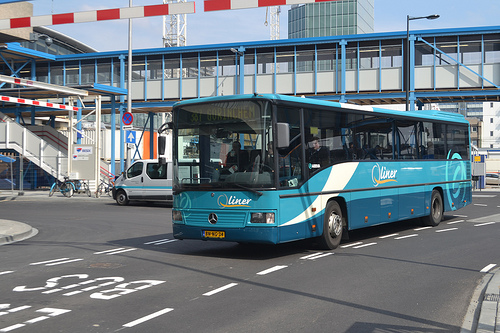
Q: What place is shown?
A: It is a road.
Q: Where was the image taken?
A: It was taken at the road.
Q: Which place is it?
A: It is a road.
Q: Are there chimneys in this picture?
A: No, there are no chimneys.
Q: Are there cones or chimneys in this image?
A: No, there are no chimneys or cones.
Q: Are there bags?
A: No, there are no bags.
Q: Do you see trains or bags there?
A: No, there are no bags or trains.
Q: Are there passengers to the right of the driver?
A: Yes, there are passengers to the right of the driver.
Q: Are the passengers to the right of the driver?
A: Yes, the passengers are to the right of the driver.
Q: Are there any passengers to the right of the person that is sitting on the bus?
A: Yes, there are passengers to the right of the person.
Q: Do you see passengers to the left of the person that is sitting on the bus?
A: No, the passengers are to the right of the person.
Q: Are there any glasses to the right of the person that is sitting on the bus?
A: No, there are passengers to the right of the person.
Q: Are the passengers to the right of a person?
A: Yes, the passengers are to the right of a person.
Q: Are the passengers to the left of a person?
A: No, the passengers are to the right of a person.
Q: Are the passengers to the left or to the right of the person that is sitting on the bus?
A: The passengers are to the right of the person.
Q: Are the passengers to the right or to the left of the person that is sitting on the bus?
A: The passengers are to the right of the person.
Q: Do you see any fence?
A: No, there are no fences.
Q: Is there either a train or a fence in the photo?
A: No, there are no fences or trains.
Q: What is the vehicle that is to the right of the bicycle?
A: The vehicle is a van.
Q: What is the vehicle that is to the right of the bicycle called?
A: The vehicle is a van.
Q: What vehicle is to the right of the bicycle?
A: The vehicle is a van.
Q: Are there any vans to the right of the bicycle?
A: Yes, there is a van to the right of the bicycle.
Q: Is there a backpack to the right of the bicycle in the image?
A: No, there is a van to the right of the bicycle.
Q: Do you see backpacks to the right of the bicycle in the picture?
A: No, there is a van to the right of the bicycle.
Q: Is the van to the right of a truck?
A: No, the van is to the right of the bicycle.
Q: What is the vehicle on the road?
A: The vehicle is a van.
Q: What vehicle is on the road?
A: The vehicle is a van.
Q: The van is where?
A: The van is on the road.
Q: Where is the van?
A: The van is on the road.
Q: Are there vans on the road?
A: Yes, there is a van on the road.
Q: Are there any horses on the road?
A: No, there is a van on the road.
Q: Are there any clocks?
A: No, there are no clocks.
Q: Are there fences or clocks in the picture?
A: No, there are no clocks or fences.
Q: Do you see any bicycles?
A: Yes, there is a bicycle.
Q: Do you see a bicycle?
A: Yes, there is a bicycle.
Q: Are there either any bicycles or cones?
A: Yes, there is a bicycle.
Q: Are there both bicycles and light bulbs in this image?
A: No, there is a bicycle but no light bulbs.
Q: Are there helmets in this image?
A: No, there are no helmets.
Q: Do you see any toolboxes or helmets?
A: No, there are no helmets or toolboxes.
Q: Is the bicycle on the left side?
A: Yes, the bicycle is on the left of the image.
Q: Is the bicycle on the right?
A: No, the bicycle is on the left of the image.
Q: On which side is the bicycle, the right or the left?
A: The bicycle is on the left of the image.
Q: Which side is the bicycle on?
A: The bicycle is on the left of the image.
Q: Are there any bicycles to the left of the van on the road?
A: Yes, there is a bicycle to the left of the van.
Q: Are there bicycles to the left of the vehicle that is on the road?
A: Yes, there is a bicycle to the left of the van.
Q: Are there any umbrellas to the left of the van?
A: No, there is a bicycle to the left of the van.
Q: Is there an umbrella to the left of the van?
A: No, there is a bicycle to the left of the van.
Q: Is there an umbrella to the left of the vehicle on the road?
A: No, there is a bicycle to the left of the van.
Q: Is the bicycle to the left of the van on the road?
A: Yes, the bicycle is to the left of the van.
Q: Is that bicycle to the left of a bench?
A: No, the bicycle is to the left of the van.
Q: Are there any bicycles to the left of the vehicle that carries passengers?
A: Yes, there is a bicycle to the left of the bus.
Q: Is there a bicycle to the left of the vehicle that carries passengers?
A: Yes, there is a bicycle to the left of the bus.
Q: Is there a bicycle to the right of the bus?
A: No, the bicycle is to the left of the bus.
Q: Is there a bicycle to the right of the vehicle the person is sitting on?
A: No, the bicycle is to the left of the bus.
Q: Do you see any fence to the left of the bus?
A: No, there is a bicycle to the left of the bus.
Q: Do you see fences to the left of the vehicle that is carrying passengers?
A: No, there is a bicycle to the left of the bus.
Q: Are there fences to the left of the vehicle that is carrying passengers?
A: No, there is a bicycle to the left of the bus.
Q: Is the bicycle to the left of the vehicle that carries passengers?
A: Yes, the bicycle is to the left of the bus.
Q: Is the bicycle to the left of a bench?
A: No, the bicycle is to the left of the bus.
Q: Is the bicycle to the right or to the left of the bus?
A: The bicycle is to the left of the bus.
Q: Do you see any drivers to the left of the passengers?
A: Yes, there is a driver to the left of the passengers.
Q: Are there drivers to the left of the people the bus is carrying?
A: Yes, there is a driver to the left of the passengers.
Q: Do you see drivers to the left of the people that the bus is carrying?
A: Yes, there is a driver to the left of the passengers.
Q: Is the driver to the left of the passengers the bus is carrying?
A: Yes, the driver is to the left of the passengers.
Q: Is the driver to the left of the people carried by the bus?
A: Yes, the driver is to the left of the passengers.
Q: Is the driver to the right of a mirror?
A: Yes, the driver is to the right of a mirror.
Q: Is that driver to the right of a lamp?
A: No, the driver is to the right of a mirror.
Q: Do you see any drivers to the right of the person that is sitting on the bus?
A: Yes, there is a driver to the right of the person.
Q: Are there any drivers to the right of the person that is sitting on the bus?
A: Yes, there is a driver to the right of the person.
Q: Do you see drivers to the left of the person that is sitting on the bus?
A: No, the driver is to the right of the person.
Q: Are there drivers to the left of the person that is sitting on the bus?
A: No, the driver is to the right of the person.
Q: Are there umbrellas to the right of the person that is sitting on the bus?
A: No, there is a driver to the right of the person.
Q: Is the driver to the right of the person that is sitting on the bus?
A: Yes, the driver is to the right of the person.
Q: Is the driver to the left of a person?
A: No, the driver is to the right of a person.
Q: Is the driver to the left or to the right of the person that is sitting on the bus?
A: The driver is to the right of the person.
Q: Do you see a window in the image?
A: Yes, there is a window.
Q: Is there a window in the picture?
A: Yes, there is a window.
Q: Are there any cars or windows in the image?
A: Yes, there is a window.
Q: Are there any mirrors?
A: Yes, there is a mirror.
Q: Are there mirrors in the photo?
A: Yes, there is a mirror.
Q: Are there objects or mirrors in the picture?
A: Yes, there is a mirror.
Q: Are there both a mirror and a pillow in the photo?
A: No, there is a mirror but no pillows.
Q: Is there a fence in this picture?
A: No, there are no fences.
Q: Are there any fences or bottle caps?
A: No, there are no fences or bottle caps.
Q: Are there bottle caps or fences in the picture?
A: No, there are no fences or bottle caps.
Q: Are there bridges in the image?
A: Yes, there is a bridge.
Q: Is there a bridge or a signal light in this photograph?
A: Yes, there is a bridge.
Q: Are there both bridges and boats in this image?
A: No, there is a bridge but no boats.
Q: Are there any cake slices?
A: No, there are no cake slices.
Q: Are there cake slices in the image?
A: No, there are no cake slices.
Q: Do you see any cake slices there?
A: No, there are no cake slices.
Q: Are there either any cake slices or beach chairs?
A: No, there are no cake slices or beach chairs.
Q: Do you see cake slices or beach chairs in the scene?
A: No, there are no cake slices or beach chairs.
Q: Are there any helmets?
A: No, there are no helmets.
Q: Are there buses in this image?
A: Yes, there is a bus.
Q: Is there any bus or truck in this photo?
A: Yes, there is a bus.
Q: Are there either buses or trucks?
A: Yes, there is a bus.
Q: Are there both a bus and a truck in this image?
A: No, there is a bus but no trucks.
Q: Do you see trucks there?
A: No, there are no trucks.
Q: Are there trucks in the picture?
A: No, there are no trucks.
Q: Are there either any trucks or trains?
A: No, there are no trucks or trains.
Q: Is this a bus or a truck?
A: This is a bus.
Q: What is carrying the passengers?
A: The bus is carrying the passengers.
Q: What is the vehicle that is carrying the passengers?
A: The vehicle is a bus.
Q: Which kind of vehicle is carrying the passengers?
A: The vehicle is a bus.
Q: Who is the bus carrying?
A: The bus is carrying passengers.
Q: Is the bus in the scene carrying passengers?
A: Yes, the bus is carrying passengers.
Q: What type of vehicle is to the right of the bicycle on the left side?
A: The vehicle is a bus.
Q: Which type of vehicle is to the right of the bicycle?
A: The vehicle is a bus.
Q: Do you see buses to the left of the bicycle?
A: No, the bus is to the right of the bicycle.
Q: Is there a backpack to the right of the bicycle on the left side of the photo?
A: No, there is a bus to the right of the bicycle.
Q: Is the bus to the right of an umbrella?
A: No, the bus is to the right of the bicycle.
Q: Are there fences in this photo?
A: No, there are no fences.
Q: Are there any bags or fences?
A: No, there are no fences or bags.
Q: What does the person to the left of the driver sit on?
A: The person sits on the bus.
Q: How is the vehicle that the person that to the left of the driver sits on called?
A: The vehicle is a bus.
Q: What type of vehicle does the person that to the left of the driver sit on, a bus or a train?
A: The person sits on a bus.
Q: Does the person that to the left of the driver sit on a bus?
A: Yes, the person sits on a bus.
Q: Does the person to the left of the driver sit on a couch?
A: No, the person sits on a bus.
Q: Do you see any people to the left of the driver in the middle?
A: Yes, there is a person to the left of the driver.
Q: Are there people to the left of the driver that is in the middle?
A: Yes, there is a person to the left of the driver.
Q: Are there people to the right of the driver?
A: No, the person is to the left of the driver.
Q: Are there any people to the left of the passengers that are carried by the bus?
A: Yes, there is a person to the left of the passengers.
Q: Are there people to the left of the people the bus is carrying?
A: Yes, there is a person to the left of the passengers.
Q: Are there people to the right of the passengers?
A: No, the person is to the left of the passengers.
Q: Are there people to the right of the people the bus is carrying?
A: No, the person is to the left of the passengers.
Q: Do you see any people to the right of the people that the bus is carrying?
A: No, the person is to the left of the passengers.